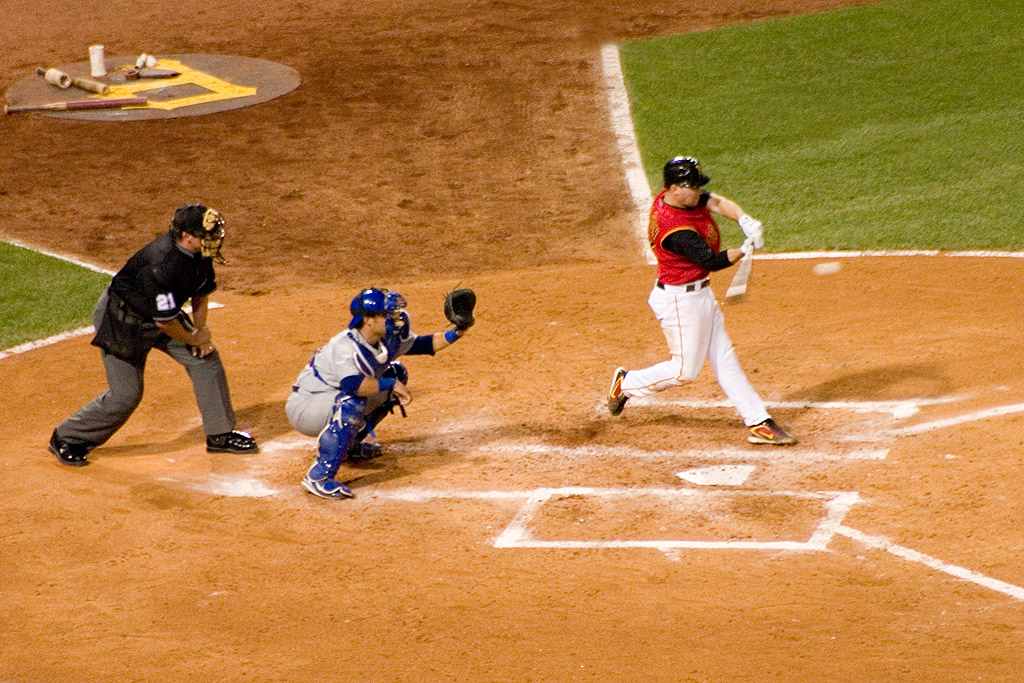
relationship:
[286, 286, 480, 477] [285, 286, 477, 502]
catcher wearing catcher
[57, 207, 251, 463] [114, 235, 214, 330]
referee wearing shirt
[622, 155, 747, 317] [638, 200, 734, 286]
batter wearing shirt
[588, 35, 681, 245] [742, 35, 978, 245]
lines separating grass